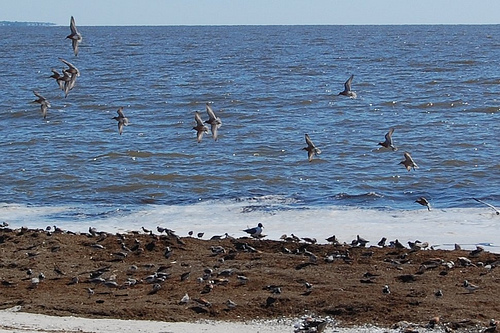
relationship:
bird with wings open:
[398, 153, 420, 175] [421, 190, 432, 203]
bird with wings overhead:
[380, 127, 399, 146] [386, 128, 395, 138]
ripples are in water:
[2, 161, 299, 192] [1, 13, 499, 256]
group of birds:
[2, 17, 442, 208] [2, 10, 441, 199]